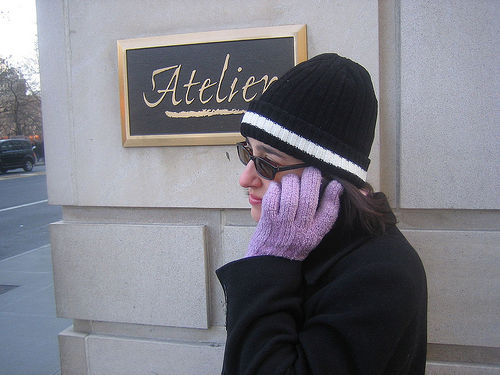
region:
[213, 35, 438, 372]
A woman holding a cellphone to her ear.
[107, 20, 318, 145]
A black and gold sign on a building.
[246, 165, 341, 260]
A lilac colored glove.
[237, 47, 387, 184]
A black knit hat with a white stripe around it.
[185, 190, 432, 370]
A black coat with a collar on it.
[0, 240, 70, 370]
Part of the sidewalk.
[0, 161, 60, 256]
The road.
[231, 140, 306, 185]
A pair of black sunglasses.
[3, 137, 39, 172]
A dark colored vehicle on the street.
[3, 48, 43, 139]
Trees bare with no leaves.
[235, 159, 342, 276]
fuzzy light purple glove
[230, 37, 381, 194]
black and white hat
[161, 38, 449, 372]
woman talking on her phone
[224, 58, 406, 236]
woman with short brown hair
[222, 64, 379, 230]
woman wearing sunglasses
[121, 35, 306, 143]
black sign with a gold border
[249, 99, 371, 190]
white stripe on a black hat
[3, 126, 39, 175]
car on the street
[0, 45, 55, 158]
tree with no leaves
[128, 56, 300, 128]
sign with gold letters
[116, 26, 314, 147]
a black and gold sign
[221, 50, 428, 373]
a woman talking on the phone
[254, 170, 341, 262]
a woman's purple glove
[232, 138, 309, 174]
glasses on a woman's face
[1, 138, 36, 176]
an suv on the street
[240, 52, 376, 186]
woman's black and white hat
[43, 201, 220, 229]
cut stone on a building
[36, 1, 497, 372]
section of a stone building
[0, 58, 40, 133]
a patch of dead trees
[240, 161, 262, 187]
a woman's nose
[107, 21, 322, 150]
A sign to a store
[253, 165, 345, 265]
A purple hand glove worn by a woman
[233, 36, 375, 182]
A black and white beanie cap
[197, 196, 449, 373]
A black trench coat worn by a lady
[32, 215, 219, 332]
A grey brick on the side of a building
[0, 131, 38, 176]
A black vehicle that is parked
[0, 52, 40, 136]
A tree with green leaves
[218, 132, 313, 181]
A pair of sunglasses worn by a woman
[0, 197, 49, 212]
A white line in the middle of the street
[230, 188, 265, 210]
A woman has pink lip gloss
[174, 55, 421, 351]
person talking on the phone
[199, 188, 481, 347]
person wearing black jacket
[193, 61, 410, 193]
person wearing black and white hat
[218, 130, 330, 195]
person's sunglasses are black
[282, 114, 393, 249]
person has dark brown hair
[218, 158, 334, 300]
woman wearing purple glove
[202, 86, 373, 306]
woman holding phone against her ear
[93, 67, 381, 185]
black sign with brown lettering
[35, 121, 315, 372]
building made of bricks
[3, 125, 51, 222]
black car parked on the road